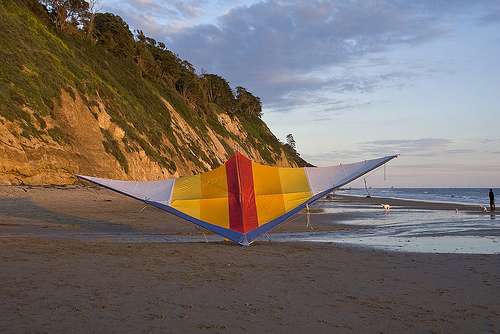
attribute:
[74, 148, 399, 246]
kite — winged, just landed, brightly colored, pointing downward, red, tipped, grey, yellow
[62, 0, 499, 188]
sky — clear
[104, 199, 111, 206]
rock — brown, big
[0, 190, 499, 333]
beach — wet, dark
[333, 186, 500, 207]
water — wavy, blue, ocean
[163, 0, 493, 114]
cloud — grey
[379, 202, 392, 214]
dog — white